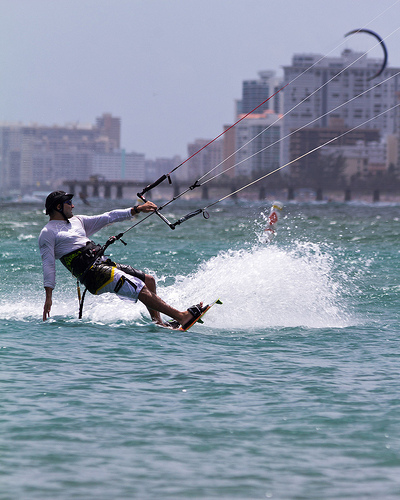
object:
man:
[38, 189, 204, 331]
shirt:
[38, 208, 133, 289]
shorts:
[76, 263, 158, 303]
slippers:
[160, 296, 211, 334]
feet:
[154, 303, 205, 336]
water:
[0, 199, 398, 499]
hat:
[43, 190, 76, 217]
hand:
[41, 299, 55, 322]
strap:
[75, 276, 89, 323]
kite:
[104, 0, 399, 251]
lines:
[177, 0, 399, 200]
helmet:
[43, 187, 70, 210]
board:
[178, 300, 219, 332]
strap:
[192, 303, 204, 321]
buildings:
[1, 48, 399, 202]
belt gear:
[61, 232, 135, 287]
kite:
[341, 29, 389, 79]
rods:
[131, 175, 209, 230]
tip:
[198, 304, 219, 319]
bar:
[129, 191, 183, 235]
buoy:
[256, 200, 286, 247]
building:
[288, 127, 390, 180]